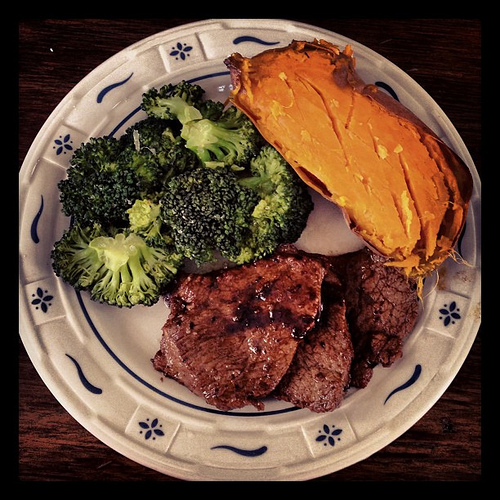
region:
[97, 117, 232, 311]
the broccoli is fresh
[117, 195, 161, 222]
the broccoli is fresh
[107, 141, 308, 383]
the broccoli is fresh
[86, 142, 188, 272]
the broccoli is fresh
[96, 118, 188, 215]
the broccoli is fresh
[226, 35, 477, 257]
a baked sweet potato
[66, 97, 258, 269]
a pile of broccoli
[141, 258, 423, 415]
some steak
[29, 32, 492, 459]
A blue and white plate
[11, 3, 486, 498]
A wooden table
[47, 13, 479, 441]
A plate of food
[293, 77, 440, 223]
scoring marks on the potato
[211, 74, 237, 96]
reflection on the plate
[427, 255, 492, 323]
some sauce on the side of the plate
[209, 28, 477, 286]
the skin on the baked sweet potato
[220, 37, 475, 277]
Baked sweet potato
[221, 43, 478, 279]
baked sweet potato on a blue and white plate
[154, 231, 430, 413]
three pieces of meat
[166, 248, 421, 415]
roasted meat with gravy on top of the first slice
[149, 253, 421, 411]
roasted meat sitting on a blue and white plate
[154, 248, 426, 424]
roasted meat sitting on a plate with broccoli and a baked sweet potato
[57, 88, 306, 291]
broccoli spears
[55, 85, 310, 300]
broccoli spears on a blue and white plate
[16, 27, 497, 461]
white plate with blue markings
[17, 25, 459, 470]
white plate holding meat, broccoli spears and a baked sweet potato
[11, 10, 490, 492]
a white dish with blue designs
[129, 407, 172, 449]
a flower on border of plate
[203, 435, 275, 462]
a curved line on plate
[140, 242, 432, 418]
three slices of meat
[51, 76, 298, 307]
pieces of broccoli are green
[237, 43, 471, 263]
sweet potato on side of plate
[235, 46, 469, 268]
a sweet potato is orange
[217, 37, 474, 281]
potato with skin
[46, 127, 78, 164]
a blue flower next to broccoli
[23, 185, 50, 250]
curved line is blue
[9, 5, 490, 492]
a white china plate with blue pattern covered with food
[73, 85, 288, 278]
a cooked serving of broccoli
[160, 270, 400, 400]
serving of several slices of cooked meat that looks like steak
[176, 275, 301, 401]
a piece of steak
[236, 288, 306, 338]
some gravy or juice on the meat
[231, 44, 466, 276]
a half of a baked sweet potato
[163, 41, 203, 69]
a blue star shaped pattern on the plate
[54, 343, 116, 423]
a blue pattern on the rim of the plate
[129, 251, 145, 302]
a stalk of broccoli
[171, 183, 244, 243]
broccoli floret